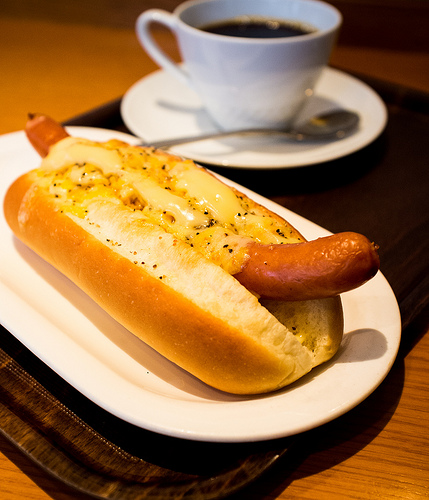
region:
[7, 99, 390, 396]
Lunch hot dog ready eat.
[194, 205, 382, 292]
Hot dog well done.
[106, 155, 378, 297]
Smothered cheese and spices.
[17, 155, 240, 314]
Toasted roll for hot dog.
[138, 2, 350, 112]
Hot cup black coffee.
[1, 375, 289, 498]
White plate brown place mat.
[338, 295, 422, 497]
Wooden table under plate.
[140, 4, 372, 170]
White cup and saucer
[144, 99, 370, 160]
Silver spoon stir coffee.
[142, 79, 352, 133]
Cup shadow shown saucer.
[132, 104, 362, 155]
a spoon on a plate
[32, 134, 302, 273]
cheese on a hot dog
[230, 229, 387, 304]
the end of a hot dog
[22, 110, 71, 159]
the far end of a hot dog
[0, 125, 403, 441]
a long oval plate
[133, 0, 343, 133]
a cup filled with coffee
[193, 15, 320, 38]
coffee in a cup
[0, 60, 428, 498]
a brown tray under the plates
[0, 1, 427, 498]
a brown wooden table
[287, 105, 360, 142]
the end of a spoon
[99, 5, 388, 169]
a cup of black coffee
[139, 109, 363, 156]
a spoon resting on a saucer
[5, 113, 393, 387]
a hot dog in a bun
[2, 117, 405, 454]
an oblong white plate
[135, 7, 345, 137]
a white coffee cup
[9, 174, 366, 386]
a hot dog bun split down the middle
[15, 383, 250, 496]
a brown food tray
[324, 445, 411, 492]
a wood grain table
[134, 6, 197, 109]
handle of a coffee mug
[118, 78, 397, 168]
saucer under the coffee cup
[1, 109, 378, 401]
A FOOT LONG HOT DOG ON A BUN WITH CHEESE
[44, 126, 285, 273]
MELTED CHEESE COVERING THE HOT DOG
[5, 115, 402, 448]
A WHITE PLATE ON A TRAY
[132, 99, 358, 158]
A METAL SPOON ON A SAUCER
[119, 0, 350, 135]
A CUP OF COFFEE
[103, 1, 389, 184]
A CUP AND SAUCER ON A TRAY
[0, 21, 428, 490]
A TRAY OF FOOD ON A TABLE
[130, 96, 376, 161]
A SPOON NEXT TO A CUP OF COFFEE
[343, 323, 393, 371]
SHADOW OF THE HOT DOG ON A PLATE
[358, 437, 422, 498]
BROWN WOODEN TABLE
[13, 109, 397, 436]
a hot dog on the white plate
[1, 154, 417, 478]
a plate on top of a tray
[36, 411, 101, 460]
a black tray on top of the table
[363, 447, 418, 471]
a brown table with food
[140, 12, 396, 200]
a cup of coffee on the plate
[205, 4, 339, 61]
a dark coffee on the cup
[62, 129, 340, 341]
cheese and black pepper on hot dog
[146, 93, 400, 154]
a spoon placed on the plate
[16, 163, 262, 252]
a yellow cheese on hot dog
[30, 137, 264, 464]
a hot dog on white plate